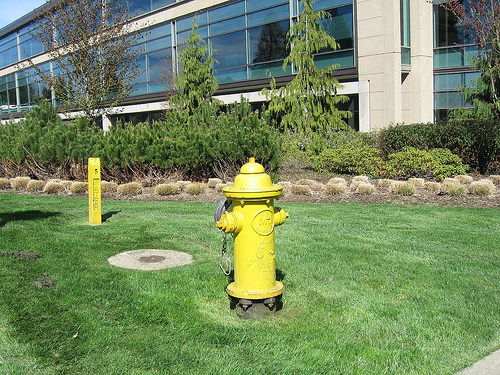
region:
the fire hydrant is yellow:
[226, 156, 283, 306]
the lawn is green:
[301, 242, 442, 364]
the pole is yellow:
[85, 156, 106, 222]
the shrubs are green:
[136, 95, 218, 170]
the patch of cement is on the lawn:
[111, 238, 198, 278]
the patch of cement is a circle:
[118, 240, 187, 282]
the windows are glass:
[213, 25, 266, 75]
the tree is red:
[458, 7, 483, 36]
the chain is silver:
[214, 242, 231, 294]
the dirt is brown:
[394, 188, 446, 208]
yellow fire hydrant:
[214, 151, 288, 326]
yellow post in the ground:
[87, 155, 104, 230]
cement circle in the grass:
[103, 238, 200, 281]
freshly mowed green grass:
[334, 220, 446, 315]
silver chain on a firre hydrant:
[216, 225, 232, 281]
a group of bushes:
[22, 80, 434, 180]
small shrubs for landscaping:
[288, 156, 496, 213]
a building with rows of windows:
[138, 15, 328, 87]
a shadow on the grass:
[5, 205, 63, 237]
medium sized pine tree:
[155, 18, 235, 199]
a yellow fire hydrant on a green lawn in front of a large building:
[26, 82, 426, 351]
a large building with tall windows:
[3, 10, 486, 125]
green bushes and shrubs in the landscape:
[6, 101, 473, 198]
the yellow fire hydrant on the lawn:
[208, 153, 293, 320]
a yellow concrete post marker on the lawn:
[80, 146, 113, 232]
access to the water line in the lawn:
[103, 243, 198, 275]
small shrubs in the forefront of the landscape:
[286, 172, 496, 202]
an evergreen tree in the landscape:
[269, 7, 349, 143]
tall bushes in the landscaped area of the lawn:
[2, 101, 291, 179]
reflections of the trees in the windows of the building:
[248, 9, 353, 68]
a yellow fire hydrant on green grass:
[207, 150, 297, 320]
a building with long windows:
[0, 2, 490, 187]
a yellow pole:
[76, 146, 106, 223]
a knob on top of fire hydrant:
[240, 150, 258, 166]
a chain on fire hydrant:
[211, 197, 236, 288]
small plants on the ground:
[291, 165, 488, 207]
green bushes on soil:
[298, 137, 470, 184]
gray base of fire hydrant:
[231, 284, 286, 324]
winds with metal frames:
[0, 2, 325, 90]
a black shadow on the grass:
[3, 200, 67, 231]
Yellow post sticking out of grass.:
[69, 149, 124, 228]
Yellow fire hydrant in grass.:
[219, 160, 289, 355]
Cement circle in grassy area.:
[119, 245, 195, 277]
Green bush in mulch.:
[393, 178, 413, 208]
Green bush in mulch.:
[328, 178, 345, 213]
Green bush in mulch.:
[472, 175, 483, 196]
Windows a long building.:
[162, 21, 370, 78]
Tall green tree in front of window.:
[285, 5, 336, 161]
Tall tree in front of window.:
[62, 12, 125, 157]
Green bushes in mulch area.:
[32, 118, 243, 177]